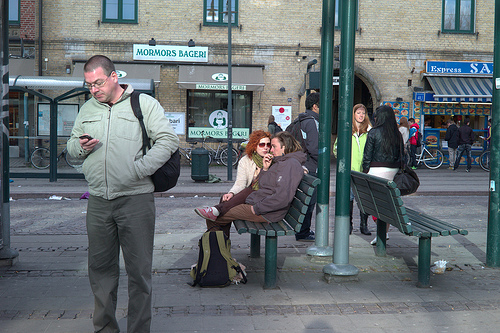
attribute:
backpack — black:
[389, 161, 436, 202]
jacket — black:
[358, 125, 404, 167]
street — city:
[1, 190, 498, 332]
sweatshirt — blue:
[254, 149, 300, 225]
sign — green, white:
[132, 40, 210, 64]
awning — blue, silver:
[410, 54, 495, 114]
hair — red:
[244, 131, 259, 153]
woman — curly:
[196, 129, 273, 224]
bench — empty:
[222, 129, 394, 260]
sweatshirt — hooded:
[255, 150, 310, 214]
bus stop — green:
[41, 58, 496, 328]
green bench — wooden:
[350, 159, 471, 271]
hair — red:
[242, 126, 265, 149]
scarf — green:
[238, 148, 264, 168]